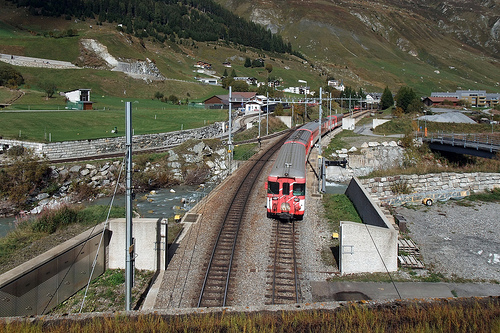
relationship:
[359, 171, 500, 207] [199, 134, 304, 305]
wall near tracks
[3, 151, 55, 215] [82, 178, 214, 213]
bushes near river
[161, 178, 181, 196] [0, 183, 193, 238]
rock in creek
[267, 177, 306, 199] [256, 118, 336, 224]
windows on train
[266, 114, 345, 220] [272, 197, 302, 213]
red train has light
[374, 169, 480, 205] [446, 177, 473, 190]
wall made of stone bricks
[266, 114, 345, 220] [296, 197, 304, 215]
red train has stripe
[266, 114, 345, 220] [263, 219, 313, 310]
red train on tracks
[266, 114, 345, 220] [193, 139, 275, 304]
red train on tracks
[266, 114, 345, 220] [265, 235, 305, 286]
red train on tracks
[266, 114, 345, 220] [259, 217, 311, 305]
red train on tracks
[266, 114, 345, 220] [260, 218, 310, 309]
red train on track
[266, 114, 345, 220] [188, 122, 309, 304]
red train on track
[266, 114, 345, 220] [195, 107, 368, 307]
red train on tracks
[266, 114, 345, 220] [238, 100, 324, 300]
red train on track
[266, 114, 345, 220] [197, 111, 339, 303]
red train on tracks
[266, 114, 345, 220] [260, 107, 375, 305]
red train on track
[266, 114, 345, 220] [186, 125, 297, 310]
red train on track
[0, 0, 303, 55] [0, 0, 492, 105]
forest on mountain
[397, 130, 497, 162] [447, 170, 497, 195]
bridge over creek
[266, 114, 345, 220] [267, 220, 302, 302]
red train on tracks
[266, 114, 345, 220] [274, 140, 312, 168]
red train carrying car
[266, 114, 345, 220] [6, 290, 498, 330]
red train going under bridge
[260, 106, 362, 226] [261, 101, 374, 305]
red train on train track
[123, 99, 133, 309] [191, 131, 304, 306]
pole next to train track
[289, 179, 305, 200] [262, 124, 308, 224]
window on train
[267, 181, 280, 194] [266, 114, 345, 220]
window on red train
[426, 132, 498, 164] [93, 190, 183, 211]
bridge over river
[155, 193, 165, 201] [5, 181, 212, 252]
water in river